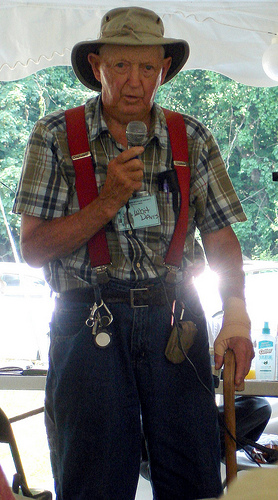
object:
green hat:
[68, 5, 191, 94]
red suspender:
[65, 102, 107, 272]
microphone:
[124, 119, 149, 146]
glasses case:
[157, 167, 180, 215]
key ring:
[85, 298, 113, 333]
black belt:
[53, 277, 192, 304]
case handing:
[171, 300, 185, 325]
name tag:
[118, 195, 161, 233]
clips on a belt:
[93, 278, 102, 303]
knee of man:
[251, 393, 273, 421]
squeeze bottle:
[255, 322, 277, 380]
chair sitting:
[0, 406, 52, 498]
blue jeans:
[44, 281, 224, 500]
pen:
[168, 178, 182, 214]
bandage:
[213, 322, 253, 350]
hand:
[101, 146, 146, 216]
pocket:
[157, 192, 187, 233]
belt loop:
[93, 288, 101, 306]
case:
[165, 320, 197, 365]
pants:
[44, 279, 222, 499]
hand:
[213, 303, 255, 386]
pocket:
[155, 186, 190, 236]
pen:
[160, 178, 168, 201]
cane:
[222, 345, 236, 484]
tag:
[112, 194, 160, 229]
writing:
[134, 205, 157, 221]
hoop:
[92, 283, 100, 308]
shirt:
[13, 94, 247, 288]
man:
[13, 7, 254, 498]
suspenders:
[162, 110, 191, 277]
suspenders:
[65, 105, 113, 267]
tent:
[1, 3, 278, 86]